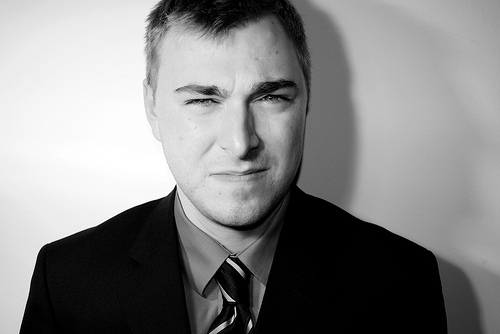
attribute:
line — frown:
[221, 69, 242, 90]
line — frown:
[241, 52, 270, 81]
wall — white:
[30, 32, 111, 133]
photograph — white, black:
[2, 4, 492, 326]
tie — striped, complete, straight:
[210, 253, 254, 332]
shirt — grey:
[181, 225, 275, 326]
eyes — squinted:
[174, 85, 298, 112]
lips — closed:
[204, 168, 274, 187]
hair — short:
[147, 2, 313, 71]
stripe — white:
[226, 259, 247, 276]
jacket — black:
[40, 200, 180, 330]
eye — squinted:
[182, 95, 220, 111]